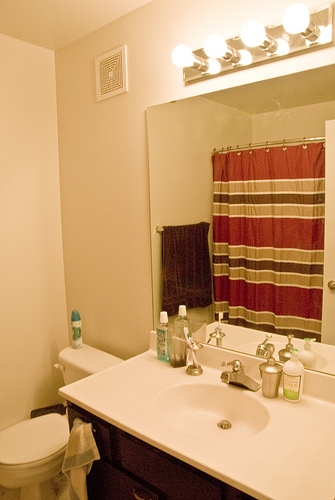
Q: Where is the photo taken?
A: Bathroom.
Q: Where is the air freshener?
A: Toilet tank.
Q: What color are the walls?
A: White.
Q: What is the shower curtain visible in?
A: Mirror.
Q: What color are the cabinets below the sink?
A: Brown.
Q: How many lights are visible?
A: Four.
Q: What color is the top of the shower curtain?
A: Red.